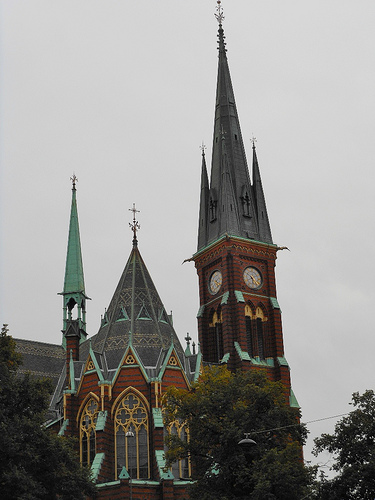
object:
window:
[244, 313, 256, 360]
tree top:
[156, 354, 314, 499]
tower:
[182, 0, 293, 385]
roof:
[85, 242, 194, 380]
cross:
[128, 202, 142, 222]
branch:
[206, 417, 218, 432]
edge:
[94, 478, 166, 488]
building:
[0, 0, 313, 500]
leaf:
[286, 439, 295, 449]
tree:
[0, 318, 103, 500]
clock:
[241, 263, 265, 291]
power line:
[244, 408, 353, 437]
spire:
[58, 167, 91, 348]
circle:
[130, 405, 148, 425]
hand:
[252, 276, 259, 286]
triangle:
[111, 342, 151, 387]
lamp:
[236, 435, 257, 449]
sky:
[0, 2, 374, 333]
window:
[111, 382, 152, 480]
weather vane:
[211, 1, 228, 30]